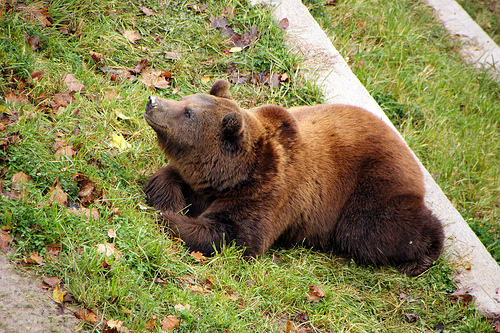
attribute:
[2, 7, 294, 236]
leaves — dead, brown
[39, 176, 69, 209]
leaf — brown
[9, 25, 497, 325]
grass — green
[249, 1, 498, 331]
step — cement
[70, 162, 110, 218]
leaf — brown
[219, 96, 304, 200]
neck — scruffy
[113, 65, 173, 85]
leaves — fallen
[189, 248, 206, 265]
leaf — brown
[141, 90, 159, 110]
nose — black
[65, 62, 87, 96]
leaf — brown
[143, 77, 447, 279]
bear — brown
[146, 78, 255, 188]
head — raised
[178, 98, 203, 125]
eye — open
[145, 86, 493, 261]
bear — brown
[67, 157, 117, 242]
leaves — brown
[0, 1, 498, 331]
grass — green